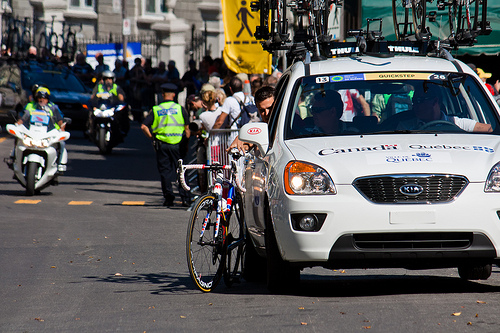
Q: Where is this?
A: This is at the road.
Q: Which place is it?
A: It is a road.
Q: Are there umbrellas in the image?
A: No, there are no umbrellas.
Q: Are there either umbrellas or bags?
A: No, there are no umbrellas or bags.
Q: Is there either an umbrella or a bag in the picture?
A: No, there are no umbrellas or bags.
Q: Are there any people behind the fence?
A: Yes, there are people behind the fence.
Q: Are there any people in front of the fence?
A: No, the people are behind the fence.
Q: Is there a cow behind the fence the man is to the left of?
A: No, there are people behind the fence.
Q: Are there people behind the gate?
A: Yes, there are people behind the gate.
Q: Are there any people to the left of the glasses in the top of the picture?
A: Yes, there are people to the left of the glasses.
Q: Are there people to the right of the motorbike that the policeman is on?
A: Yes, there are people to the right of the motorcycle.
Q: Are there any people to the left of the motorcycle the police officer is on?
A: No, the people are to the right of the motorcycle.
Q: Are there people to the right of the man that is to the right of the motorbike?
A: Yes, there are people to the right of the man.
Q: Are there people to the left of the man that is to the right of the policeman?
A: No, the people are to the right of the man.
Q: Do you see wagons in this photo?
A: No, there are no wagons.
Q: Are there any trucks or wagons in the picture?
A: No, there are no wagons or trucks.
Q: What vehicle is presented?
A: The vehicle is a car.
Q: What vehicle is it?
A: The vehicle is a car.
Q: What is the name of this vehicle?
A: That is a car.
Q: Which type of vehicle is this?
A: That is a car.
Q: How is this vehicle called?
A: That is a car.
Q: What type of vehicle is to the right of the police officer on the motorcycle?
A: The vehicle is a car.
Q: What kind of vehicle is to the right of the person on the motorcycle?
A: The vehicle is a car.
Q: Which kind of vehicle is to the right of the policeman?
A: The vehicle is a car.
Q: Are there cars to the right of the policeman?
A: Yes, there is a car to the right of the policeman.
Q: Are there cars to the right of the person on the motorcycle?
A: Yes, there is a car to the right of the policeman.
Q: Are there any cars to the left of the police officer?
A: No, the car is to the right of the police officer.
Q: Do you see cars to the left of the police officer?
A: No, the car is to the right of the police officer.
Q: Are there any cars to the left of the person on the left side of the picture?
A: No, the car is to the right of the police officer.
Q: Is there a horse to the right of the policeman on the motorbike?
A: No, there is a car to the right of the policeman.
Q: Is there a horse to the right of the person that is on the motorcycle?
A: No, there is a car to the right of the policeman.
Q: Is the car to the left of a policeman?
A: No, the car is to the right of a policeman.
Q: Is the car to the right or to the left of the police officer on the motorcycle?
A: The car is to the right of the police officer.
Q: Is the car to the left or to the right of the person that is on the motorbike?
A: The car is to the right of the police officer.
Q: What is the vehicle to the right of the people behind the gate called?
A: The vehicle is a car.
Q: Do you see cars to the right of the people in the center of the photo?
A: Yes, there is a car to the right of the people.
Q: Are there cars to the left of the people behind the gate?
A: No, the car is to the right of the people.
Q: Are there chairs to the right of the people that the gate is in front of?
A: No, there is a car to the right of the people.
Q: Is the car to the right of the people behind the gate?
A: Yes, the car is to the right of the people.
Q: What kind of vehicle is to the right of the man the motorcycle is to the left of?
A: The vehicle is a car.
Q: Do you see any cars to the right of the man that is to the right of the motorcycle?
A: Yes, there is a car to the right of the man.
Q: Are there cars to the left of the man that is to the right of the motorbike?
A: No, the car is to the right of the man.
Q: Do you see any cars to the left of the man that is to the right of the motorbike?
A: No, the car is to the right of the man.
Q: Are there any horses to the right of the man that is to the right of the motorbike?
A: No, there is a car to the right of the man.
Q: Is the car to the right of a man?
A: Yes, the car is to the right of a man.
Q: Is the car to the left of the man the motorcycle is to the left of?
A: No, the car is to the right of the man.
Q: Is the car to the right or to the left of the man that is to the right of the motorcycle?
A: The car is to the right of the man.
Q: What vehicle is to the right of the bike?
A: The vehicle is a car.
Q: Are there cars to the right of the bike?
A: Yes, there is a car to the right of the bike.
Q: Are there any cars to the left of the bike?
A: No, the car is to the right of the bike.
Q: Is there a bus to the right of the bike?
A: No, there is a car to the right of the bike.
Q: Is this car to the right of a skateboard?
A: No, the car is to the right of the bike.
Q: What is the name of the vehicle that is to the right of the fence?
A: The vehicle is a car.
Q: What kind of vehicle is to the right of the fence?
A: The vehicle is a car.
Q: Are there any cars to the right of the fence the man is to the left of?
A: Yes, there is a car to the right of the fence.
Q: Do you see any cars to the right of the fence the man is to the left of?
A: Yes, there is a car to the right of the fence.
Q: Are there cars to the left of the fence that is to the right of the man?
A: No, the car is to the right of the fence.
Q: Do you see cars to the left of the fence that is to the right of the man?
A: No, the car is to the right of the fence.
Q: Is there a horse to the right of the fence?
A: No, there is a car to the right of the fence.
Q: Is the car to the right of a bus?
A: No, the car is to the right of the fence.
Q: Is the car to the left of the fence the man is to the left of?
A: No, the car is to the right of the fence.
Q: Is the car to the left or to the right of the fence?
A: The car is to the right of the fence.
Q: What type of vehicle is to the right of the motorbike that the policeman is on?
A: The vehicle is a car.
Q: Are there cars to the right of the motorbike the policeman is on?
A: Yes, there is a car to the right of the motorcycle.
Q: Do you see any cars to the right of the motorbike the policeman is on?
A: Yes, there is a car to the right of the motorcycle.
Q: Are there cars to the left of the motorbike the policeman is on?
A: No, the car is to the right of the motorcycle.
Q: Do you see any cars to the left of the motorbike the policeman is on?
A: No, the car is to the right of the motorcycle.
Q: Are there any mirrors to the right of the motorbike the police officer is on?
A: No, there is a car to the right of the motorbike.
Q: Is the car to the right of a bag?
A: No, the car is to the right of the motorbike.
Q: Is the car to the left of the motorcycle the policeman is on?
A: No, the car is to the right of the motorcycle.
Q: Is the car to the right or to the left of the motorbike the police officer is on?
A: The car is to the right of the motorbike.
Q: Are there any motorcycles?
A: Yes, there is a motorcycle.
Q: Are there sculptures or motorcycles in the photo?
A: Yes, there is a motorcycle.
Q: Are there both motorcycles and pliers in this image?
A: No, there is a motorcycle but no pliers.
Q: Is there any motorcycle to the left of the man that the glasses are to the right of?
A: Yes, there is a motorcycle to the left of the man.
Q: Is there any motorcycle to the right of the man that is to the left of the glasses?
A: No, the motorcycle is to the left of the man.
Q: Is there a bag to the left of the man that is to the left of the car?
A: No, there is a motorcycle to the left of the man.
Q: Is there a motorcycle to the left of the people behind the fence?
A: Yes, there is a motorcycle to the left of the people.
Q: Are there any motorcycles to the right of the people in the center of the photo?
A: No, the motorcycle is to the left of the people.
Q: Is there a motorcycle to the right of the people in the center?
A: No, the motorcycle is to the left of the people.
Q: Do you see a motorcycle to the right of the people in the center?
A: No, the motorcycle is to the left of the people.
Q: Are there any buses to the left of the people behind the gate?
A: No, there is a motorcycle to the left of the people.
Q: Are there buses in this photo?
A: No, there are no buses.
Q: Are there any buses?
A: No, there are no buses.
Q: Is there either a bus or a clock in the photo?
A: No, there are no buses or clocks.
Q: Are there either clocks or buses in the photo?
A: No, there are no buses or clocks.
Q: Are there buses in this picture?
A: No, there are no buses.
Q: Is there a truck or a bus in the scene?
A: No, there are no buses or trucks.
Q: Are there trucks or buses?
A: No, there are no buses or trucks.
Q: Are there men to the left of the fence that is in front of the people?
A: Yes, there is a man to the left of the fence.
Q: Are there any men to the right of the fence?
A: No, the man is to the left of the fence.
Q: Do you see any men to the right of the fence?
A: No, the man is to the left of the fence.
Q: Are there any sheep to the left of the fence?
A: No, there is a man to the left of the fence.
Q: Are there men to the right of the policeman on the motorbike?
A: Yes, there is a man to the right of the policeman.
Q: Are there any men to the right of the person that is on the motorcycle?
A: Yes, there is a man to the right of the policeman.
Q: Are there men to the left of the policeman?
A: No, the man is to the right of the policeman.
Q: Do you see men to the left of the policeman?
A: No, the man is to the right of the policeman.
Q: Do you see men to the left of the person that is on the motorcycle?
A: No, the man is to the right of the policeman.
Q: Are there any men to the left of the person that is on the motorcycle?
A: No, the man is to the right of the policeman.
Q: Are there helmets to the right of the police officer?
A: No, there is a man to the right of the police officer.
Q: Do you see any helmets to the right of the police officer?
A: No, there is a man to the right of the police officer.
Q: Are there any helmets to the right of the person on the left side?
A: No, there is a man to the right of the police officer.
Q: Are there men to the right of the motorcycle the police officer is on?
A: Yes, there is a man to the right of the motorbike.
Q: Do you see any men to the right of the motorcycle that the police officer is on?
A: Yes, there is a man to the right of the motorbike.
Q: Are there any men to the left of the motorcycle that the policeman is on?
A: No, the man is to the right of the motorcycle.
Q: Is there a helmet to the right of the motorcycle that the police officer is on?
A: No, there is a man to the right of the motorbike.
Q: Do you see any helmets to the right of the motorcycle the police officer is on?
A: No, there is a man to the right of the motorbike.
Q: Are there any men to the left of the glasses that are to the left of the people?
A: Yes, there is a man to the left of the glasses.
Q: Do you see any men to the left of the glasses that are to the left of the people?
A: Yes, there is a man to the left of the glasses.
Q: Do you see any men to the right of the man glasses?
A: No, the man is to the left of the glasses.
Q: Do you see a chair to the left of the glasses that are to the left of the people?
A: No, there is a man to the left of the glasses.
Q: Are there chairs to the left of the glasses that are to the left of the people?
A: No, there is a man to the left of the glasses.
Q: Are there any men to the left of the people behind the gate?
A: Yes, there is a man to the left of the people.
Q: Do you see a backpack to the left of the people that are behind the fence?
A: No, there is a man to the left of the people.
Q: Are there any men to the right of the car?
A: No, the man is to the left of the car.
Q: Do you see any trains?
A: No, there are no trains.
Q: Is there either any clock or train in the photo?
A: No, there are no trains or clocks.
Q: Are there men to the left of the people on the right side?
A: Yes, there is a man to the left of the people.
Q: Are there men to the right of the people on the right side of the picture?
A: No, the man is to the left of the people.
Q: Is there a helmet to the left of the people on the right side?
A: No, there is a man to the left of the people.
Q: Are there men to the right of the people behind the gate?
A: Yes, there is a man to the right of the people.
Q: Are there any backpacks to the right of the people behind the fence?
A: No, there is a man to the right of the people.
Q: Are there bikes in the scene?
A: Yes, there is a bike.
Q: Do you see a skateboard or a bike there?
A: Yes, there is a bike.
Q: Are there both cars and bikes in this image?
A: Yes, there are both a bike and a car.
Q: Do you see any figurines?
A: No, there are no figurines.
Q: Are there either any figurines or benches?
A: No, there are no figurines or benches.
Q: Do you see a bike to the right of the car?
A: No, the bike is to the left of the car.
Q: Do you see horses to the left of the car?
A: No, there is a bike to the left of the car.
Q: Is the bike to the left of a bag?
A: No, the bike is to the left of the car.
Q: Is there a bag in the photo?
A: No, there are no bags.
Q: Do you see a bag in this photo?
A: No, there are no bags.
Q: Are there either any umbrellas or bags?
A: No, there are no bags or umbrellas.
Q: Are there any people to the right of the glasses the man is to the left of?
A: Yes, there are people to the right of the glasses.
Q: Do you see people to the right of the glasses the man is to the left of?
A: Yes, there are people to the right of the glasses.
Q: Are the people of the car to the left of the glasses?
A: No, the people are to the right of the glasses.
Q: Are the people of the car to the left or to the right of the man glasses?
A: The people are to the right of the glasses.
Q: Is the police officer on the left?
A: Yes, the police officer is on the left of the image.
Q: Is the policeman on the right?
A: No, the policeman is on the left of the image.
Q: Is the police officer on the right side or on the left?
A: The police officer is on the left of the image.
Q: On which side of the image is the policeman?
A: The policeman is on the left of the image.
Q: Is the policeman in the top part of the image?
A: Yes, the policeman is in the top of the image.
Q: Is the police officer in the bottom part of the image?
A: No, the police officer is in the top of the image.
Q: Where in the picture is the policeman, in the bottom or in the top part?
A: The policeman is in the top of the image.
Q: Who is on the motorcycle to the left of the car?
A: The police officer is on the motorcycle.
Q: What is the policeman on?
A: The policeman is on the motorbike.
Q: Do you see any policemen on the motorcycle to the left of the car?
A: Yes, there is a policeman on the motorbike.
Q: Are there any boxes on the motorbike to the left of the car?
A: No, there is a policeman on the motorbike.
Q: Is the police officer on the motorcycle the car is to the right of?
A: Yes, the police officer is on the motorcycle.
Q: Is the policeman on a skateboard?
A: No, the policeman is on the motorcycle.